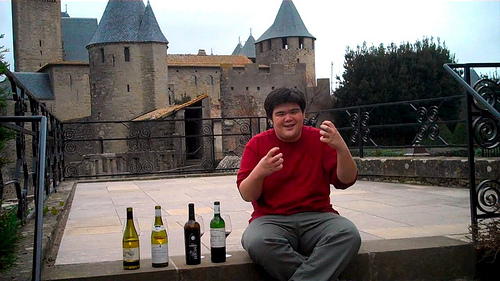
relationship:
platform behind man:
[352, 180, 471, 232] [229, 77, 366, 279]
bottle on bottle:
[121, 206, 141, 270] [150, 205, 170, 267]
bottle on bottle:
[121, 206, 141, 270] [183, 204, 201, 264]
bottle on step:
[121, 206, 141, 270] [38, 234, 499, 279]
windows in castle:
[94, 36, 172, 83] [51, 36, 229, 98]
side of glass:
[209, 216, 228, 269] [200, 190, 240, 258]